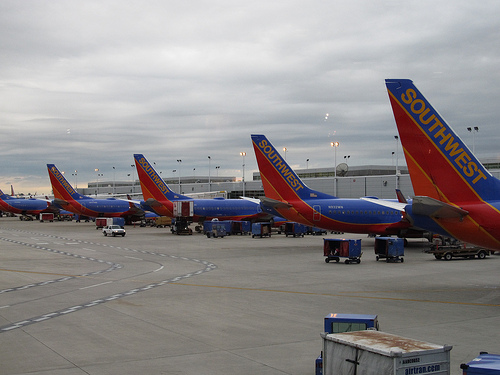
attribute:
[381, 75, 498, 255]
airplane — southwest airlines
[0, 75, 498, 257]
planes — Southwest Airlines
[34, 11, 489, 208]
sky — cloudy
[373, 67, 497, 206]
wing — red, blue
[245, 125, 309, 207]
wing — red, blue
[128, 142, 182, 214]
wing — red, blue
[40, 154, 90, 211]
wing — red, blue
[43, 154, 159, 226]
airplane — red, blue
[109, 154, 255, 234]
plane — red, blue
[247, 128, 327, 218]
wing — back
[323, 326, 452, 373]
container — white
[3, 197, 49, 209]
wing — red, blue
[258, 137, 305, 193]
word — Southwest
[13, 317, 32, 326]
line — black, white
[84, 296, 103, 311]
line — black, white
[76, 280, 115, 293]
line — black, white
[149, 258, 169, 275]
line — black, white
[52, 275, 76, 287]
line — black, white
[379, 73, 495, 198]
airplane wing — blue, red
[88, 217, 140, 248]
car — white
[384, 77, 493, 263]
plane — Southwest Airlines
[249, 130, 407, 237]
plane — Southwest Airlines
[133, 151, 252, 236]
plane — Southwest Airlines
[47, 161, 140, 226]
plane — Southwest Airlines